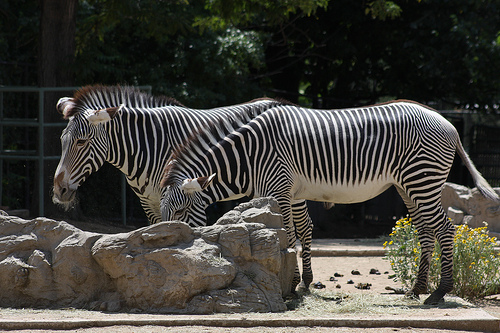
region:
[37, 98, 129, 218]
the head of a zebra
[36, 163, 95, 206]
the nose of a zebra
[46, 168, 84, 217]
the nose of a zebra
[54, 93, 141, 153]
the ears of a zebra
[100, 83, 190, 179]
the neck of a zebra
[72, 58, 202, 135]
the main of a zebra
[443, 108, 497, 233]
the tail of a zebra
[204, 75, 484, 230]
the body of a zebra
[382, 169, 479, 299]
the legs of a zebra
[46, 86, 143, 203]
the head of a zebra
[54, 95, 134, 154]
the ear of a zebra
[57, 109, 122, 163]
the eye of a zebra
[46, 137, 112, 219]
the nose of a zebra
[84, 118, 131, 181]
the jaw of a zebra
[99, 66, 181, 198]
the neck of a zebra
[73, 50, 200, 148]
the main of a zebra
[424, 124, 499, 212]
the tail of a zebra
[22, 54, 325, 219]
the body of a zebra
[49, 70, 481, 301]
Two zebras standing in a zoo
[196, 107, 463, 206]
The zebras are black and white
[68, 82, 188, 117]
The short mane of the zebra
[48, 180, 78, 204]
A brown nose on the zebra's face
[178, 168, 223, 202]
A black and white ear on the zebra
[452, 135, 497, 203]
A swinging tail on the zebra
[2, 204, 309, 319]
A rocky outcropping by the zebras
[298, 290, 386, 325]
A small patch of grass on the ground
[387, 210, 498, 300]
A group of yellow flowers on the ground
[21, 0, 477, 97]
Many green trees behind the zebras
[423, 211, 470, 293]
leg of a zebra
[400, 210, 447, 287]
of a zebra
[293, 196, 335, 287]
of a zebra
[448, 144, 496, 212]
tail of a zebra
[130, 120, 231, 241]
head of a zebra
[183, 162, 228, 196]
ear of a zebra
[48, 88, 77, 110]
ear of a zebra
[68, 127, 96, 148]
eye of a zebra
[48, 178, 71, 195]
nose of a zebra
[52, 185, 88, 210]
mouth of a zebra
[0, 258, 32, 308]
rock on the ground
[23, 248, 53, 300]
rock on the ground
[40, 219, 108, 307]
rock on the ground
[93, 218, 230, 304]
rock on the ground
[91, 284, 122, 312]
rock on the ground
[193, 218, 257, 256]
rock on the ground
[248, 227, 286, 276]
rock on the ground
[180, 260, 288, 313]
rock on the ground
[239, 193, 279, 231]
rock on the ground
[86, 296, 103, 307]
rock on the ground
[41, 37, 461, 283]
black and white zebras